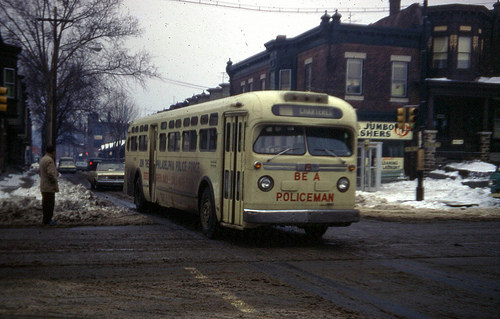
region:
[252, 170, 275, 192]
head light on a bus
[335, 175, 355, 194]
head light on a bus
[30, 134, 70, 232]
person on the street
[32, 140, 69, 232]
person wearing brown coat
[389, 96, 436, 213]
street light in the snow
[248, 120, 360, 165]
windshield on a bus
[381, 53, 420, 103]
window on a building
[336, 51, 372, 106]
window on a building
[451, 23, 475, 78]
window on a building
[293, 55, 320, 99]
window on a building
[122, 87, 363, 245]
Old charter bus driving down the street.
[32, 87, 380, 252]
Man waiting for charter bus.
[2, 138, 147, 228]
Man standing by snow covered embankment.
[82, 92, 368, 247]
Car stuck behind an old charter bus.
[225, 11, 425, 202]
Store selling Jumbo Kosher dogs.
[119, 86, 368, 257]
Charter bus advertising becoming a police man.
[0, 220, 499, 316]
Snow is melting on the city streets.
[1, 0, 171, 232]
Man waiting for bus by a tree that has lost it's leaves.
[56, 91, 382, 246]
Traffic on a busy city street.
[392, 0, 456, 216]
Traffic light an intersection.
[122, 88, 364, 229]
a large yellow bus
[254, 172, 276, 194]
the headlight of the bus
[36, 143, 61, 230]
a man standing on the street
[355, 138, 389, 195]
a telephone booth in the snow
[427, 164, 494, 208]
snow on the steps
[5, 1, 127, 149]
a tree without leaves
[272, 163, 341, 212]
words on the front of the bus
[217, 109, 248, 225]
these are the door of the bus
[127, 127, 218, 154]
six windows on the bus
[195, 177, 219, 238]
front tire of the bus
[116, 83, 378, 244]
the bus is white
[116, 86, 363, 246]
the bus is very dirty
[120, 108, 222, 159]
the bus has many windows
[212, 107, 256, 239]
the bus has a door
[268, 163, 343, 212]
the front of the bus says BE A POLICEMAN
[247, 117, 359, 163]
the bus has a windshield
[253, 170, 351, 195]
the bus has round lights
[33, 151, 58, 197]
the man is wearing a tan jacket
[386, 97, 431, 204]
this is a traffic light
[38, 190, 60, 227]
the man is wearing black pants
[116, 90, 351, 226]
old yellow school bus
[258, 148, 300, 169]
windshield wiper on front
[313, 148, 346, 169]
windshield wiper on bus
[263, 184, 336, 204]
logo on front of bus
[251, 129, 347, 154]
front windshield on bus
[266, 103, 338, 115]
electronic digital sign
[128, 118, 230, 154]
side windows on bus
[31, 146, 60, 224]
man standing on street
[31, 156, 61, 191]
large brown jacket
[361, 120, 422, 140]
white sign with lettering on it